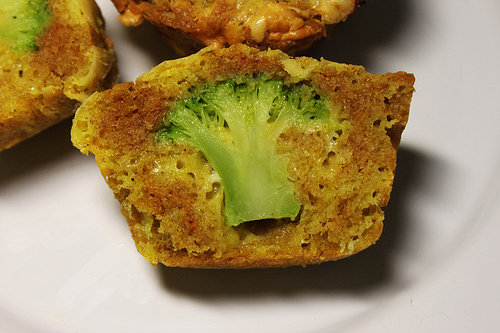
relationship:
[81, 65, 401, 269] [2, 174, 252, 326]
muffin on plate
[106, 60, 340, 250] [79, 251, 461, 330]
brea on plate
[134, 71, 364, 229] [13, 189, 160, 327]
muffin on plate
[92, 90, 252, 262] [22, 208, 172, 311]
bread on plate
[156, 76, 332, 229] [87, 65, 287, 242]
broccoli in muffin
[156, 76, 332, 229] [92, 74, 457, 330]
broccoli in muffin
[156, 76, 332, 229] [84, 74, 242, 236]
broccoli in bread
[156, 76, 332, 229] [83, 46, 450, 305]
broccoli in bread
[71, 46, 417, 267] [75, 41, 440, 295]
brea of bread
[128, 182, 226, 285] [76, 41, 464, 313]
holes in food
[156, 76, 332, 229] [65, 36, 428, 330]
broccoli in food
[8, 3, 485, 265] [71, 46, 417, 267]
group of brea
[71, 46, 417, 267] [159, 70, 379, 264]
brea with brocolli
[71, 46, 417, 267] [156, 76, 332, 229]
brea with broccoli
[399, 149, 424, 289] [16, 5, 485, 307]
black shadow on plate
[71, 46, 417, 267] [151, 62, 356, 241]
brea with brocolli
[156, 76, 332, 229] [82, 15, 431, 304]
broccoli inside cupcake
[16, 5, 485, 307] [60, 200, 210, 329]
plate made of wood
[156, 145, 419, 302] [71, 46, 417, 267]
shadow of brea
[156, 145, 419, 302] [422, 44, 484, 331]
shadow on table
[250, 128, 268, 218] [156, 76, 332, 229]
inside of broccoli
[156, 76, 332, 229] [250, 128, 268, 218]
broccoli has inside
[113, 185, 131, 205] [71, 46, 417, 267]
hole inside brea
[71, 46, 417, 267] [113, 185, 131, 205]
brea has hole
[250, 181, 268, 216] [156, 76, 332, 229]
white of broccoli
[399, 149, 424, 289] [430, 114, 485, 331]
black shadow on white table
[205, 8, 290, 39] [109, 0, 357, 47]
crust on cupcake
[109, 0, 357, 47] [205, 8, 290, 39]
cupcake has crust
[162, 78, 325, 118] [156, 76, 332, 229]
green top of broccoli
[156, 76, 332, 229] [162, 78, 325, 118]
broccoli has green top